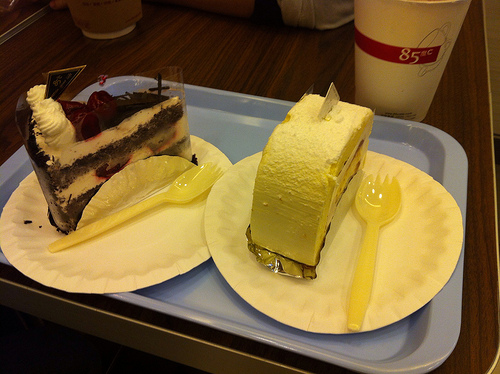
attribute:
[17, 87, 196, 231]
cake — sliced, layered, chocolate, brown, creamy, cream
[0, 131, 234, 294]
plate — paper, white, cream color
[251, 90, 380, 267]
cake — yellow, big, white, layered, cream color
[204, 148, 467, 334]
plate — paper, white, cream color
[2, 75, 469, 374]
tray — purple, plastic, blue, flat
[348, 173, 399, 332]
utensil — plastic, yellow, spork, spoon, cream color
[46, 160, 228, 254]
utensil — plastic, yellow, spork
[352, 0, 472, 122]
cup — paper, disposable, white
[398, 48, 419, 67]
number — white, 85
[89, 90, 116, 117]
cherry — cooked, red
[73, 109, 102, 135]
cherry — cooked, red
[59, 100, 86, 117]
cherry — cooked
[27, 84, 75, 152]
topping — whipped cream, white, cream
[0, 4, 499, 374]
table — brown, wooden